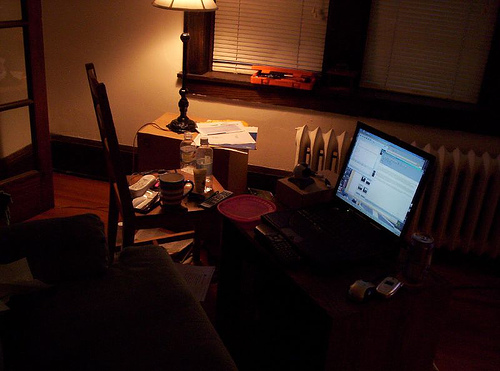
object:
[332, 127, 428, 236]
screen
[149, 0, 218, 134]
lamp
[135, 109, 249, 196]
table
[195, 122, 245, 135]
papers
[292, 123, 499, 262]
radiator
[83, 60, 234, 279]
chair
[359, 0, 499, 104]
blinds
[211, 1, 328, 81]
blinds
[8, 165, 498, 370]
floor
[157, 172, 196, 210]
coffee mug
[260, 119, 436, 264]
laptop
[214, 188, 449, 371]
desk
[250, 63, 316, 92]
tools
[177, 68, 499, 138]
window sill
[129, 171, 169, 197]
cordless phone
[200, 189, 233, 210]
remote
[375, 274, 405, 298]
cellphone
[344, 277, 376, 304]
mouse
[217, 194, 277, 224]
plate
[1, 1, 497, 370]
room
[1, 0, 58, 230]
door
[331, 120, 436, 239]
monitor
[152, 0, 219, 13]
shade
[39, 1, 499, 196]
wall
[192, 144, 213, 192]
bottle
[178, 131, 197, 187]
bottle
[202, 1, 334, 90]
window